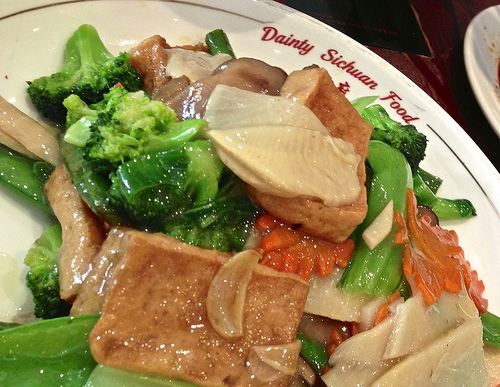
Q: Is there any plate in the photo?
A: Yes, there is a plate.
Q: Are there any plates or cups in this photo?
A: Yes, there is a plate.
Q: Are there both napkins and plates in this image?
A: No, there is a plate but no napkins.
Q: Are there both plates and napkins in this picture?
A: No, there is a plate but no napkins.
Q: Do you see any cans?
A: No, there are no cans.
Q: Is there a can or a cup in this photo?
A: No, there are no cans or cups.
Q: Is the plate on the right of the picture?
A: Yes, the plate is on the right of the image.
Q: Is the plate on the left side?
A: No, the plate is on the right of the image.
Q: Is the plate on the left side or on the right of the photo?
A: The plate is on the right of the image.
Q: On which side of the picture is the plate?
A: The plate is on the right of the image.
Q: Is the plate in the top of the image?
A: Yes, the plate is in the top of the image.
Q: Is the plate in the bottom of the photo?
A: No, the plate is in the top of the image.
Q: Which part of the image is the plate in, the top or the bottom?
A: The plate is in the top of the image.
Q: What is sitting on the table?
A: The plate is sitting on the table.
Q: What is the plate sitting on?
A: The plate is sitting on the table.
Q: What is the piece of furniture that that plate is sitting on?
A: The piece of furniture is a table.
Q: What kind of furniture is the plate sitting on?
A: The plate is sitting on the table.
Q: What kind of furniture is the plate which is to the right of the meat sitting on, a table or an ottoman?
A: The plate is sitting on a table.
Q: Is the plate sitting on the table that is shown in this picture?
A: Yes, the plate is sitting on the table.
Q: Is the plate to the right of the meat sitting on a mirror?
A: No, the plate is sitting on the table.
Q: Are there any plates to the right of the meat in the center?
A: Yes, there is a plate to the right of the meat.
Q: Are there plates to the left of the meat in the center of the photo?
A: No, the plate is to the right of the meat.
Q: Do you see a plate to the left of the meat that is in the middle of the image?
A: No, the plate is to the right of the meat.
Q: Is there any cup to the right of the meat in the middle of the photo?
A: No, there is a plate to the right of the meat.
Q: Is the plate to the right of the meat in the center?
A: Yes, the plate is to the right of the meat.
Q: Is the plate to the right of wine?
A: No, the plate is to the right of the meat.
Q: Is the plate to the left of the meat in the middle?
A: No, the plate is to the right of the meat.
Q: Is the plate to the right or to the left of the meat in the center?
A: The plate is to the right of the meat.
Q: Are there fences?
A: No, there are no fences.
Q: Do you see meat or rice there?
A: Yes, there is meat.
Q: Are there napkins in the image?
A: No, there are no napkins.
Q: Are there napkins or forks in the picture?
A: No, there are no napkins or forks.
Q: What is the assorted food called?
A: The food is meat.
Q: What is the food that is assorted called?
A: The food is meat.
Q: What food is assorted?
A: The food is meat.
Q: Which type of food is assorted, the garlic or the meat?
A: The meat is assorted.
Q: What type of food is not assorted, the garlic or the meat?
A: The garlic is not assorted.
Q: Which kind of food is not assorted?
A: The food is garlic.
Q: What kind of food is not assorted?
A: The food is garlic.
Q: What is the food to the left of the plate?
A: The food is meat.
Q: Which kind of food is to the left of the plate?
A: The food is meat.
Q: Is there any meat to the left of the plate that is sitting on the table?
A: Yes, there is meat to the left of the plate.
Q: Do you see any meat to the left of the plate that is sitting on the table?
A: Yes, there is meat to the left of the plate.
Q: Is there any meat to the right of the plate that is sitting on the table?
A: No, the meat is to the left of the plate.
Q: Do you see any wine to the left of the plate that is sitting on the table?
A: No, there is meat to the left of the plate.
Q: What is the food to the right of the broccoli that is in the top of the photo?
A: The food is meat.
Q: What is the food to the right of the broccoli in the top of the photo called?
A: The food is meat.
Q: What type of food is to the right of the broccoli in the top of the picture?
A: The food is meat.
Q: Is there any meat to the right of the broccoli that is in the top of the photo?
A: Yes, there is meat to the right of the broccoli.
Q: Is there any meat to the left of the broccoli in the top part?
A: No, the meat is to the right of the broccoli.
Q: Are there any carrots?
A: Yes, there is a carrot.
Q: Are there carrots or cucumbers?
A: Yes, there is a carrot.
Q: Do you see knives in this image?
A: No, there are no knives.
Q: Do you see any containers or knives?
A: No, there are no knives or containers.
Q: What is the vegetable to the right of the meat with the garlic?
A: The vegetable is a carrot.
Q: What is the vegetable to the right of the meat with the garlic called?
A: The vegetable is a carrot.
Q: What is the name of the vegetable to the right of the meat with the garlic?
A: The vegetable is a carrot.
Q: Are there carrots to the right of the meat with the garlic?
A: Yes, there is a carrot to the right of the meat.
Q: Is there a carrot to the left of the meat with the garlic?
A: No, the carrot is to the right of the meat.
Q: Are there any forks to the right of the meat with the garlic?
A: No, there is a carrot to the right of the meat.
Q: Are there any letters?
A: Yes, there are letters.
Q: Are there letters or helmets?
A: Yes, there are letters.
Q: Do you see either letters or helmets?
A: Yes, there are letters.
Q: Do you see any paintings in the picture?
A: No, there are no paintings.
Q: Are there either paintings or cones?
A: No, there are no paintings or cones.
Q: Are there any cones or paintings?
A: No, there are no paintings or cones.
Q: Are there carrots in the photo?
A: Yes, there is a carrot.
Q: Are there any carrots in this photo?
A: Yes, there is a carrot.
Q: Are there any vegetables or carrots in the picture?
A: Yes, there is a carrot.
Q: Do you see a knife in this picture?
A: No, there are no knives.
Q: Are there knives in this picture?
A: No, there are no knives.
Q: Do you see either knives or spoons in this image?
A: No, there are no knives or spoons.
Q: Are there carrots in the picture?
A: Yes, there is a carrot.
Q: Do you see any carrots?
A: Yes, there is a carrot.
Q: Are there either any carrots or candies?
A: Yes, there is a carrot.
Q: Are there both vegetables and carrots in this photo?
A: Yes, there are both a carrot and a vegetable.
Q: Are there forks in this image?
A: No, there are no forks.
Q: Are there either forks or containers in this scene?
A: No, there are no forks or containers.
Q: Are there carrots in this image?
A: Yes, there is a carrot.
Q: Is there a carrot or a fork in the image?
A: Yes, there is a carrot.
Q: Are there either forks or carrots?
A: Yes, there is a carrot.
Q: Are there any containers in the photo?
A: No, there are no containers.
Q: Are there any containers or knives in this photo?
A: No, there are no containers or knives.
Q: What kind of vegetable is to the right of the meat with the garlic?
A: The vegetable is a carrot.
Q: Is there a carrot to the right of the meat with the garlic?
A: Yes, there is a carrot to the right of the meat.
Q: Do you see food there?
A: Yes, there is food.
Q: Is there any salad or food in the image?
A: Yes, there is food.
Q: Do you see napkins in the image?
A: No, there are no napkins.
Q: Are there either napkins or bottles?
A: No, there are no napkins or bottles.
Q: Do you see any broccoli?
A: Yes, there is broccoli.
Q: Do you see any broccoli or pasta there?
A: Yes, there is broccoli.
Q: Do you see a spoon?
A: No, there are no spoons.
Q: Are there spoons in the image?
A: No, there are no spoons.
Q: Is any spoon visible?
A: No, there are no spoons.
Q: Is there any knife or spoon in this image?
A: No, there are no spoons or knives.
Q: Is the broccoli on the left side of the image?
A: Yes, the broccoli is on the left of the image.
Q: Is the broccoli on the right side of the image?
A: No, the broccoli is on the left of the image.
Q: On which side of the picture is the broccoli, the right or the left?
A: The broccoli is on the left of the image.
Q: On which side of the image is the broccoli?
A: The broccoli is on the left of the image.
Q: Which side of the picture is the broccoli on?
A: The broccoli is on the left of the image.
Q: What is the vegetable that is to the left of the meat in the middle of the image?
A: The vegetable is broccoli.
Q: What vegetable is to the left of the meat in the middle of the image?
A: The vegetable is broccoli.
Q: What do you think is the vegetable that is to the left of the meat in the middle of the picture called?
A: The vegetable is broccoli.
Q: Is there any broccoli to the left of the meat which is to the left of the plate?
A: Yes, there is broccoli to the left of the meat.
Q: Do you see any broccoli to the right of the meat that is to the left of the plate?
A: No, the broccoli is to the left of the meat.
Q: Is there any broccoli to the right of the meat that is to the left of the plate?
A: No, the broccoli is to the left of the meat.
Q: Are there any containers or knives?
A: No, there are no knives or containers.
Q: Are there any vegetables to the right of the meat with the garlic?
A: Yes, there is a vegetable to the right of the meat.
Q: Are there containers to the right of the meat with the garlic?
A: No, there is a vegetable to the right of the meat.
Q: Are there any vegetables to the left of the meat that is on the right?
A: Yes, there is a vegetable to the left of the meat.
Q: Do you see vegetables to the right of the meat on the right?
A: No, the vegetable is to the left of the meat.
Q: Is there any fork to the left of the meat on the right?
A: No, there is a vegetable to the left of the meat.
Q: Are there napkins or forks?
A: No, there are no napkins or forks.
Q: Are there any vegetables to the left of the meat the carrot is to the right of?
A: Yes, there is a vegetable to the left of the meat.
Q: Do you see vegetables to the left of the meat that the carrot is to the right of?
A: Yes, there is a vegetable to the left of the meat.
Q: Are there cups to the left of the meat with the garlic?
A: No, there is a vegetable to the left of the meat.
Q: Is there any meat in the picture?
A: Yes, there is meat.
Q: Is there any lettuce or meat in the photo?
A: Yes, there is meat.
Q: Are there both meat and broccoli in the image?
A: Yes, there are both meat and broccoli.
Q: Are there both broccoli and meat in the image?
A: Yes, there are both meat and broccoli.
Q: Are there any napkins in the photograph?
A: No, there are no napkins.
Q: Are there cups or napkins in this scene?
A: No, there are no napkins or cups.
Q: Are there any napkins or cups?
A: No, there are no napkins or cups.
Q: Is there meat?
A: Yes, there is meat.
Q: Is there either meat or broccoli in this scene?
A: Yes, there is meat.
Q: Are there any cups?
A: No, there are no cups.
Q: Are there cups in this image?
A: No, there are no cups.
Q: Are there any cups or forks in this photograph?
A: No, there are no cups or forks.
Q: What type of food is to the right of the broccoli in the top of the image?
A: The food is meat.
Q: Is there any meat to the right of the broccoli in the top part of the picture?
A: Yes, there is meat to the right of the broccoli.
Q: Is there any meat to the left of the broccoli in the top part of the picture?
A: No, the meat is to the right of the broccoli.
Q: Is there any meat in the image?
A: Yes, there is meat.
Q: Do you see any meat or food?
A: Yes, there is meat.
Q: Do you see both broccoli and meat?
A: Yes, there are both meat and broccoli.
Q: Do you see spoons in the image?
A: No, there are no spoons.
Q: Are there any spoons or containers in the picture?
A: No, there are no spoons or containers.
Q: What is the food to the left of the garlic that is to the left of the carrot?
A: The food is meat.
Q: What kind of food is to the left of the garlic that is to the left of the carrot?
A: The food is meat.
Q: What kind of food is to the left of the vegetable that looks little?
A: The food is meat.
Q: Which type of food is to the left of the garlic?
A: The food is meat.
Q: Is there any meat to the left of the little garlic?
A: Yes, there is meat to the left of the garlic.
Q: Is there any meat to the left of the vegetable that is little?
A: Yes, there is meat to the left of the garlic.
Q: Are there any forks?
A: No, there are no forks.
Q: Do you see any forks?
A: No, there are no forks.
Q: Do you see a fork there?
A: No, there are no forks.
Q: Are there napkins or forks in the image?
A: No, there are no forks or napkins.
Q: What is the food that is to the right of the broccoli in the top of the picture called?
A: The food is meat.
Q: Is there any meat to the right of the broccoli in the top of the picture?
A: Yes, there is meat to the right of the broccoli.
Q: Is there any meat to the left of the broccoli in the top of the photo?
A: No, the meat is to the right of the broccoli.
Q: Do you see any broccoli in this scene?
A: Yes, there is broccoli.